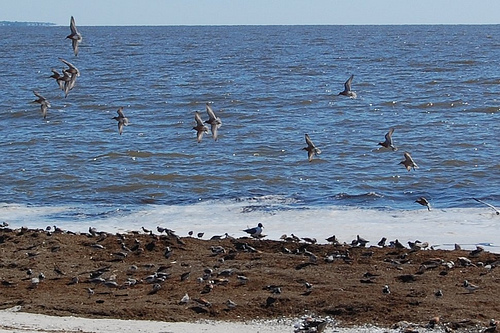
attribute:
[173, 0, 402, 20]
sky — clear, blue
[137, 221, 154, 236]
white bird — SMALL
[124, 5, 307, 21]
clouds — white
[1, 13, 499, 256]
water — dark blue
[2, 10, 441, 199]
birds — flying